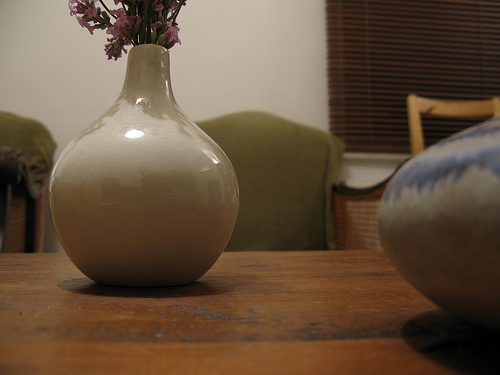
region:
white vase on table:
[33, 48, 263, 300]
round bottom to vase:
[44, 67, 237, 299]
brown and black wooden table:
[76, 313, 349, 374]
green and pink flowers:
[65, 0, 187, 55]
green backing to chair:
[186, 103, 358, 280]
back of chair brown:
[0, 93, 69, 210]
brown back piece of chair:
[385, 93, 479, 128]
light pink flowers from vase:
[105, 15, 141, 60]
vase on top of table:
[15, 118, 304, 343]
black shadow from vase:
[15, 270, 97, 315]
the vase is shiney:
[38, 39, 250, 286]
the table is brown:
[272, 270, 359, 331]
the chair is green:
[239, 103, 369, 240]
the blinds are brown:
[332, 4, 493, 90]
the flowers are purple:
[99, 8, 182, 42]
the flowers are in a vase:
[65, 1, 185, 47]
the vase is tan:
[0, 76, 273, 292]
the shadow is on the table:
[412, 315, 447, 356]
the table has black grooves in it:
[181, 302, 239, 330]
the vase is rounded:
[362, 124, 499, 311]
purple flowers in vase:
[60, 0, 188, 60]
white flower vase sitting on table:
[45, 41, 260, 301]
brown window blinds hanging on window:
[326, 2, 496, 94]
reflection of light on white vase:
[112, 101, 168, 163]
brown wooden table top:
[5, 285, 401, 372]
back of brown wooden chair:
[391, 85, 491, 145]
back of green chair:
[181, 105, 343, 251]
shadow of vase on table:
[52, 263, 264, 314]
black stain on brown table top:
[271, 305, 423, 350]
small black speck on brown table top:
[9, 302, 35, 325]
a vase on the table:
[34, 0, 266, 315]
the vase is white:
[29, 22, 264, 319]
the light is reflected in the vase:
[104, 108, 168, 157]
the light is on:
[97, 101, 164, 148]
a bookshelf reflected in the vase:
[47, 118, 94, 214]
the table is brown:
[34, 270, 364, 368]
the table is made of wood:
[157, 252, 354, 370]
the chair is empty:
[157, 90, 351, 255]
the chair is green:
[172, 82, 349, 271]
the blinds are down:
[318, 0, 473, 152]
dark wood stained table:
[237, 263, 358, 353]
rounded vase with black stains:
[368, 110, 485, 311]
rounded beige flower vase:
[18, 43, 265, 295]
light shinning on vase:
[108, 117, 176, 177]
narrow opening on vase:
[121, 36, 189, 120]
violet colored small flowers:
[65, 2, 200, 62]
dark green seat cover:
[245, 103, 354, 249]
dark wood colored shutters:
[318, 0, 453, 78]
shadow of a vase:
[41, 259, 285, 320]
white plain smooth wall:
[205, 8, 315, 91]